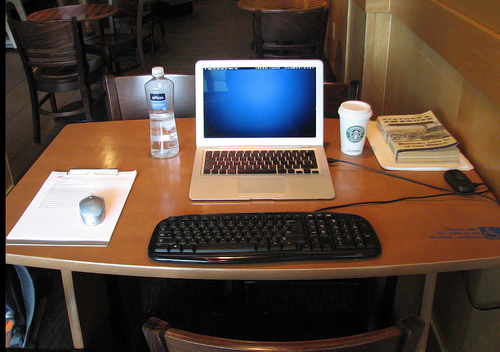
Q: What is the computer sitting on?
A: A light brown desk.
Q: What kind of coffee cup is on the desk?
A: Starbucks.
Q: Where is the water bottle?
A: To the left of the laptop.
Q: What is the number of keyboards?
A: Two.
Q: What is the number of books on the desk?
A: One.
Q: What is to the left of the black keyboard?
A: A pad of paper and mouse.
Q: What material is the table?
A: Wood.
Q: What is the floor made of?
A: Dark brown wood.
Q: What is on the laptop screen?
A: Blue light.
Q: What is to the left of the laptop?
A: A water bottle.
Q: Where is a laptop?
A: On a table.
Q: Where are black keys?
A: On black keyboard.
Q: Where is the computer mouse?
A: On the clipboard.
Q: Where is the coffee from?
A: Starbucks.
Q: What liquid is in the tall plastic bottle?
A: Water.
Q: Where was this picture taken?
A: Coffee shop.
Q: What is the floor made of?
A: Wood.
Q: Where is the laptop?
A: On the wood table.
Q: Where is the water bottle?
A: On the left side of lap top.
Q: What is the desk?
A: A laptop.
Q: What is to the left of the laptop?
A: A bottle of water.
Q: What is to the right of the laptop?
A: A cup of coffee.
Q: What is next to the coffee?
A: Books.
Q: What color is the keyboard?
A: Black.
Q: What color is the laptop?
A: Grey.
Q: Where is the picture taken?
A: In a dining area.